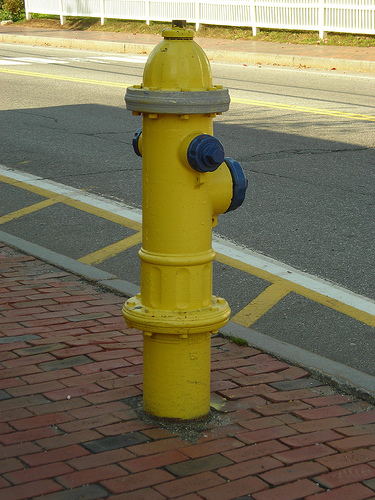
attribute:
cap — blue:
[224, 158, 248, 209]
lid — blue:
[185, 133, 229, 173]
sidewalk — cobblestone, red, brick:
[2, 227, 375, 497]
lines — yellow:
[2, 175, 141, 293]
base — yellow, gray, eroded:
[136, 389, 220, 435]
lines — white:
[0, 57, 147, 71]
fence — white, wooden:
[18, 1, 373, 42]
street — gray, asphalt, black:
[1, 42, 374, 373]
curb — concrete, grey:
[0, 228, 140, 296]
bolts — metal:
[131, 126, 145, 160]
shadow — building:
[2, 97, 372, 372]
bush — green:
[2, 1, 27, 19]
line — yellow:
[234, 92, 373, 126]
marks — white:
[42, 57, 108, 70]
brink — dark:
[74, 62, 122, 79]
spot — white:
[54, 387, 81, 412]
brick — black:
[82, 427, 150, 461]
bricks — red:
[5, 335, 123, 454]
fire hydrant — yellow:
[123, 15, 242, 422]